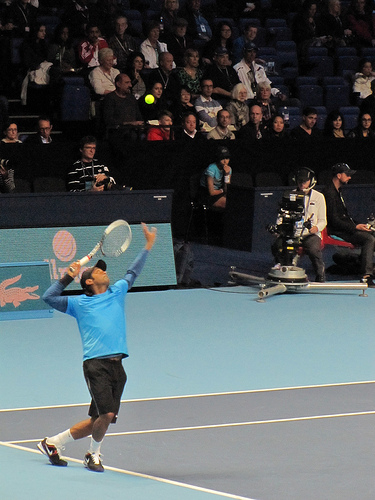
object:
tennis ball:
[145, 94, 154, 104]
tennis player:
[37, 223, 158, 474]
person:
[269, 167, 328, 282]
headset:
[290, 168, 317, 191]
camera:
[264, 195, 310, 265]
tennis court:
[0, 280, 373, 499]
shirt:
[63, 281, 132, 359]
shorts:
[83, 359, 127, 424]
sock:
[49, 428, 76, 449]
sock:
[87, 435, 104, 459]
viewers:
[0, 120, 26, 178]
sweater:
[67, 160, 116, 192]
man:
[321, 162, 374, 288]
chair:
[321, 228, 358, 272]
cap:
[331, 162, 357, 177]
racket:
[70, 219, 134, 272]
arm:
[41, 275, 71, 316]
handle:
[70, 243, 101, 271]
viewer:
[198, 147, 232, 209]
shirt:
[200, 164, 232, 190]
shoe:
[37, 437, 69, 467]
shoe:
[83, 453, 105, 473]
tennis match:
[1, 218, 373, 499]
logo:
[0, 273, 41, 309]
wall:
[0, 190, 177, 292]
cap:
[81, 259, 108, 289]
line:
[0, 380, 374, 413]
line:
[2, 410, 375, 446]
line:
[0, 440, 252, 499]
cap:
[296, 166, 315, 182]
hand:
[66, 260, 80, 278]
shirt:
[276, 189, 326, 238]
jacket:
[276, 188, 327, 238]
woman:
[2, 121, 26, 180]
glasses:
[8, 127, 17, 133]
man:
[24, 118, 66, 175]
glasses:
[39, 127, 51, 132]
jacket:
[321, 181, 356, 238]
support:
[228, 264, 369, 303]